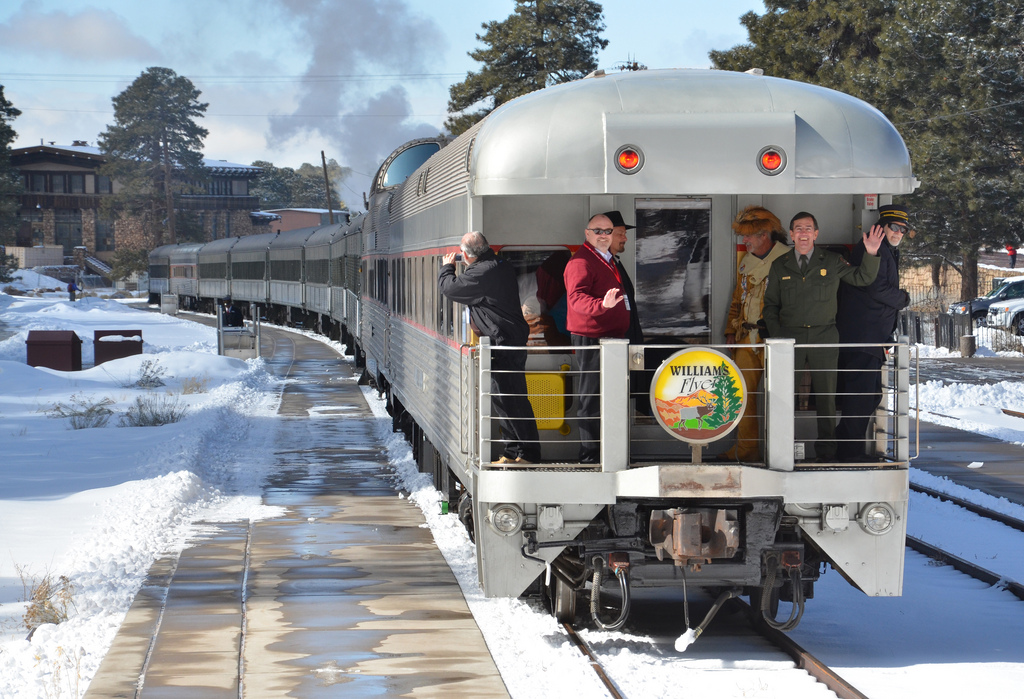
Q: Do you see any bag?
A: No, there are no bags.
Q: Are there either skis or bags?
A: No, there are no bags or skis.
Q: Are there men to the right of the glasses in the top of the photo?
A: Yes, there is a man to the right of the glasses.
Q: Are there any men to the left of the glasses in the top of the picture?
A: No, the man is to the right of the glasses.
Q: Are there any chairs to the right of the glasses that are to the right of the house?
A: No, there is a man to the right of the glasses.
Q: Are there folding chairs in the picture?
A: No, there are no folding chairs.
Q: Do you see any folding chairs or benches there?
A: No, there are no folding chairs or benches.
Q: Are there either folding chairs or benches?
A: No, there are no folding chairs or benches.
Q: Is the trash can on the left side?
A: Yes, the trash can is on the left of the image.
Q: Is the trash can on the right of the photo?
A: No, the trash can is on the left of the image.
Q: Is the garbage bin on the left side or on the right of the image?
A: The garbage bin is on the left of the image.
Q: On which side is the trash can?
A: The trash can is on the left of the image.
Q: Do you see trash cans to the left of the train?
A: Yes, there is a trash can to the left of the train.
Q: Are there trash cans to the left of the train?
A: Yes, there is a trash can to the left of the train.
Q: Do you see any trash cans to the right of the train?
A: No, the trash can is to the left of the train.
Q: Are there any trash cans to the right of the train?
A: No, the trash can is to the left of the train.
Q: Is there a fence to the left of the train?
A: No, there is a trash can to the left of the train.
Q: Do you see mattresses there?
A: No, there are no mattresses.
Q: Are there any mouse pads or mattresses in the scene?
A: No, there are no mattresses or mouse pads.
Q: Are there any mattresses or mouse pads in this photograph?
A: No, there are no mattresses or mouse pads.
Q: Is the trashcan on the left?
A: Yes, the trashcan is on the left of the image.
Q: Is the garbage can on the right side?
A: No, the garbage can is on the left of the image.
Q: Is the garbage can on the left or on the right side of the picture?
A: The garbage can is on the left of the image.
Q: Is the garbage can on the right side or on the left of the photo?
A: The garbage can is on the left of the image.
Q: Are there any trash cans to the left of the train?
A: Yes, there is a trash can to the left of the train.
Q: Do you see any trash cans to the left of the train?
A: Yes, there is a trash can to the left of the train.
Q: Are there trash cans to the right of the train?
A: No, the trash can is to the left of the train.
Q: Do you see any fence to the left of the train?
A: No, there is a trash can to the left of the train.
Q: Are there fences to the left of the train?
A: No, there is a trash can to the left of the train.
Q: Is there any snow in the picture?
A: Yes, there is snow.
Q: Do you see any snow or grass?
A: Yes, there is snow.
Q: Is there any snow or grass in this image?
A: Yes, there is snow.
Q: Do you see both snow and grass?
A: No, there is snow but no grass.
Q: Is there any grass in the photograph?
A: No, there is no grass.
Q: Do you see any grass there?
A: No, there is no grass.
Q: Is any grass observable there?
A: No, there is no grass.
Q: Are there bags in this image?
A: No, there are no bags.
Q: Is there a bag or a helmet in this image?
A: No, there are no bags or helmets.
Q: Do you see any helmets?
A: No, there are no helmets.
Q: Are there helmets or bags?
A: No, there are no helmets or bags.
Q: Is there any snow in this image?
A: Yes, there is snow.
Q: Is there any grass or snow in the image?
A: Yes, there is snow.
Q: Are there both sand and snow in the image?
A: No, there is snow but no sand.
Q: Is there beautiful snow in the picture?
A: Yes, there is beautiful snow.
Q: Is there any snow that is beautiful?
A: Yes, there is snow that is beautiful.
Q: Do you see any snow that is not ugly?
A: Yes, there is beautiful snow.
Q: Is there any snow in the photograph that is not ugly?
A: Yes, there is beautiful snow.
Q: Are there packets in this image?
A: No, there are no packets.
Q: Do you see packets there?
A: No, there are no packets.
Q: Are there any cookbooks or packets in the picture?
A: No, there are no packets or cookbooks.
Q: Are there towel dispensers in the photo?
A: No, there are no towel dispensers.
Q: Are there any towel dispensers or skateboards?
A: No, there are no towel dispensers or skateboards.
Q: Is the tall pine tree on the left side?
A: Yes, the pine tree is on the left of the image.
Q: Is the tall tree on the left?
A: Yes, the pine tree is on the left of the image.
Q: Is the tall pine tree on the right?
A: No, the pine tree is on the left of the image.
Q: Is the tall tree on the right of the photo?
A: No, the pine tree is on the left of the image.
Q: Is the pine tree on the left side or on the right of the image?
A: The pine tree is on the left of the image.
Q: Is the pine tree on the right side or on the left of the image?
A: The pine tree is on the left of the image.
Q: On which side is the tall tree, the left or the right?
A: The pine tree is on the left of the image.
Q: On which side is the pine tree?
A: The pine tree is on the left of the image.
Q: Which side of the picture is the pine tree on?
A: The pine tree is on the left of the image.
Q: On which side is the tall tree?
A: The pine tree is on the left of the image.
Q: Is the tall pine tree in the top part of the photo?
A: Yes, the pine is in the top of the image.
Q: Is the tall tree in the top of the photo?
A: Yes, the pine is in the top of the image.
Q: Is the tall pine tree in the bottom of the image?
A: No, the pine tree is in the top of the image.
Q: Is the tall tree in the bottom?
A: No, the pine tree is in the top of the image.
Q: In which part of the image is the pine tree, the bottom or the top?
A: The pine tree is in the top of the image.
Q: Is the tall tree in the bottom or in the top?
A: The pine tree is in the top of the image.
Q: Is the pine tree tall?
A: Yes, the pine tree is tall.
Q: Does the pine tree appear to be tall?
A: Yes, the pine tree is tall.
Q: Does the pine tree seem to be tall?
A: Yes, the pine tree is tall.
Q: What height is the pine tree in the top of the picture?
A: The pine tree is tall.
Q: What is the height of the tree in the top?
A: The pine tree is tall.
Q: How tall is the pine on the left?
A: The pine is tall.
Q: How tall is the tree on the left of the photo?
A: The pine is tall.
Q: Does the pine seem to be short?
A: No, the pine is tall.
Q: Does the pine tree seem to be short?
A: No, the pine tree is tall.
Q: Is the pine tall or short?
A: The pine is tall.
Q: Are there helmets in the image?
A: No, there are no helmets.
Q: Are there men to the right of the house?
A: Yes, there is a man to the right of the house.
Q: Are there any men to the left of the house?
A: No, the man is to the right of the house.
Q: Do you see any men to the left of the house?
A: No, the man is to the right of the house.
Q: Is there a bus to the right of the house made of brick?
A: No, there is a man to the right of the house.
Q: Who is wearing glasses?
A: The man is wearing glasses.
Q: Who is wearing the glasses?
A: The man is wearing glasses.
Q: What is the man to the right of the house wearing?
A: The man is wearing glasses.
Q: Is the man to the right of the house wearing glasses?
A: Yes, the man is wearing glasses.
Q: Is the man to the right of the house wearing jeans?
A: No, the man is wearing glasses.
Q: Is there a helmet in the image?
A: No, there are no helmets.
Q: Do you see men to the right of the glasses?
A: Yes, there is a man to the right of the glasses.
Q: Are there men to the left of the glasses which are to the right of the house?
A: No, the man is to the right of the glasses.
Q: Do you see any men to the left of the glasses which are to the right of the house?
A: No, the man is to the right of the glasses.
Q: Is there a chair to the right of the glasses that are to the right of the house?
A: No, there is a man to the right of the glasses.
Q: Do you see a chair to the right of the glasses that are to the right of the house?
A: No, there is a man to the right of the glasses.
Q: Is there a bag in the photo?
A: No, there are no bags.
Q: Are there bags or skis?
A: No, there are no bags or skis.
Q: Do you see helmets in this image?
A: No, there are no helmets.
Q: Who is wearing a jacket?
A: The man is wearing a jacket.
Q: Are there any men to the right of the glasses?
A: Yes, there is a man to the right of the glasses.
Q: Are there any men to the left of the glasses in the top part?
A: No, the man is to the right of the glasses.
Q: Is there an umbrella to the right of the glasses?
A: No, there is a man to the right of the glasses.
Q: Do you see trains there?
A: Yes, there is a train.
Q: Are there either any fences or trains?
A: Yes, there is a train.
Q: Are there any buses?
A: No, there are no buses.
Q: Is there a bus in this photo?
A: No, there are no buses.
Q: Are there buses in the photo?
A: No, there are no buses.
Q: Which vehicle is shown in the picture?
A: The vehicle is a train.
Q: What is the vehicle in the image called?
A: The vehicle is a train.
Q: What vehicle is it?
A: The vehicle is a train.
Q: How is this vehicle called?
A: This is a train.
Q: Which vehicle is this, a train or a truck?
A: This is a train.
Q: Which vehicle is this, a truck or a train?
A: This is a train.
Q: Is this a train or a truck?
A: This is a train.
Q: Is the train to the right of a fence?
A: No, the train is to the right of the trashcan.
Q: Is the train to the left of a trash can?
A: No, the train is to the right of a trash can.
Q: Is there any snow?
A: Yes, there is snow.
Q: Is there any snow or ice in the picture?
A: Yes, there is snow.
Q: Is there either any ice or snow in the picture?
A: Yes, there is snow.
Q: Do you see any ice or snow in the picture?
A: Yes, there is snow.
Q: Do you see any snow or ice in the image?
A: Yes, there is snow.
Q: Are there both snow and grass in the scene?
A: No, there is snow but no grass.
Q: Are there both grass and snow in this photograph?
A: No, there is snow but no grass.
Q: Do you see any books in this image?
A: No, there are no books.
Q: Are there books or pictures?
A: No, there are no books or pictures.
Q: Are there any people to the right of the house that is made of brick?
A: Yes, there are people to the right of the house.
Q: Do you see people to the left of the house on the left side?
A: No, the people are to the right of the house.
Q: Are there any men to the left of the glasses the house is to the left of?
A: No, the man is to the right of the glasses.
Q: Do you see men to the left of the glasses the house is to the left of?
A: No, the man is to the right of the glasses.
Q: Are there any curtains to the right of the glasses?
A: No, there is a man to the right of the glasses.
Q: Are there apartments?
A: No, there are no apartments.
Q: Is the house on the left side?
A: Yes, the house is on the left of the image.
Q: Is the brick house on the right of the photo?
A: No, the house is on the left of the image.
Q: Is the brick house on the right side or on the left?
A: The house is on the left of the image.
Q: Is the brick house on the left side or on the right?
A: The house is on the left of the image.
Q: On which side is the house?
A: The house is on the left of the image.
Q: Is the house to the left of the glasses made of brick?
A: Yes, the house is made of brick.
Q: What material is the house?
A: The house is made of brick.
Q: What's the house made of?
A: The house is made of brick.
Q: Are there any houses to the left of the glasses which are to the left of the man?
A: Yes, there is a house to the left of the glasses.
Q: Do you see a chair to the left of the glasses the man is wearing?
A: No, there is a house to the left of the glasses.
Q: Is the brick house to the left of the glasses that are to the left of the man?
A: Yes, the house is to the left of the glasses.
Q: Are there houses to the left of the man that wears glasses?
A: Yes, there is a house to the left of the man.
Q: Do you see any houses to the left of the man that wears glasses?
A: Yes, there is a house to the left of the man.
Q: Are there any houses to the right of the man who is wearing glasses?
A: No, the house is to the left of the man.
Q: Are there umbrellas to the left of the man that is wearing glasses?
A: No, there is a house to the left of the man.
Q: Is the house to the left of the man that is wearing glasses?
A: Yes, the house is to the left of the man.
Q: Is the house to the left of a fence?
A: No, the house is to the left of the man.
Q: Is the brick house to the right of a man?
A: No, the house is to the left of a man.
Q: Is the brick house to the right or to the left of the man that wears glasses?
A: The house is to the left of the man.